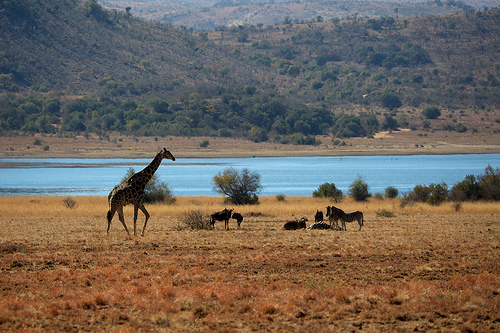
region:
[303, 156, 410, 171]
the water is blue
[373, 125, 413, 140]
red dirt on ground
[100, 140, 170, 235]
a giraffe walking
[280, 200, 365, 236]
animals in the field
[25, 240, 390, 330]
the brown grass in field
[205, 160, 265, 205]
a small green bush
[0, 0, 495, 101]
hills in the horizon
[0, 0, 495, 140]
bushes are all over the wilderness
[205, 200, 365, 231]
the baby animals are small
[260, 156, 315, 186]
the baby waves in water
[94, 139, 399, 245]
animals in the plains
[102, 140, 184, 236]
wild giraffe in the plains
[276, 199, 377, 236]
animals near a dead animal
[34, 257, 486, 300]
brown grasses of a plain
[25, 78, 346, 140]
green trees beyond the water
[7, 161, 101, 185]
blue water of a river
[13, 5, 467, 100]
grassy hills in the distance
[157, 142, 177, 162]
head of a giraffe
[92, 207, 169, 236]
legs of a giraffe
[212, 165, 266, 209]
bushes on the plains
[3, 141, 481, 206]
the water is blue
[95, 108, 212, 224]
the giraffe is walking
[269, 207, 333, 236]
animals are laying down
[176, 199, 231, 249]
tumble weed in the grass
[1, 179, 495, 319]
the grass is brown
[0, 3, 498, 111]
hills are coverd in trees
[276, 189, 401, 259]
animals are in a herd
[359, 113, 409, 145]
dirt path in grass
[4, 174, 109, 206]
reflection on the water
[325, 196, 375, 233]
animals are standing still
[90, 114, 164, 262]
a giraffe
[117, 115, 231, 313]
a giraffe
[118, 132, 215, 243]
a giraffe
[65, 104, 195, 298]
a giraffe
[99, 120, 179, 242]
giraffe on the land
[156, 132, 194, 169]
head of the animal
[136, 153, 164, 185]
neck of the giraffe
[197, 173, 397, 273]
animals on the ground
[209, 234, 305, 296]
yellow ground below the animals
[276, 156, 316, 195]
water in the background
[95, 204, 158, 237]
legs of the animal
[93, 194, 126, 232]
tail of the animal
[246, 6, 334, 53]
trees in the distance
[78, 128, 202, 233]
giraffe facing the right